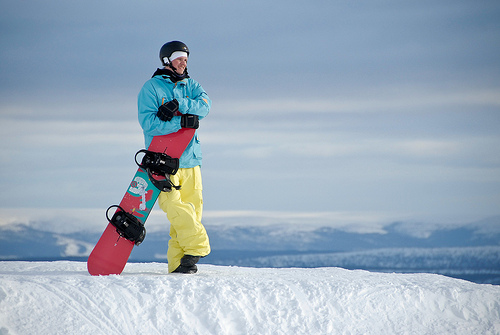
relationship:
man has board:
[127, 29, 221, 281] [89, 112, 199, 281]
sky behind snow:
[4, 0, 492, 273] [2, 255, 497, 333]